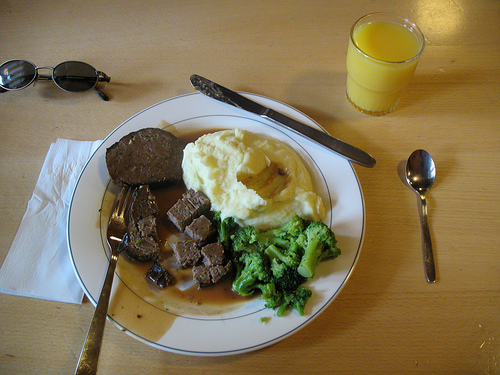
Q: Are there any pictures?
A: No, there are no pictures.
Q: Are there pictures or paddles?
A: No, there are no pictures or paddles.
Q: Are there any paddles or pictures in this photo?
A: No, there are no pictures or paddles.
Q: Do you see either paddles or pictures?
A: No, there are no pictures or paddles.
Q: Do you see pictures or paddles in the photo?
A: No, there are no pictures or paddles.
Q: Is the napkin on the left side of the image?
A: Yes, the napkin is on the left of the image.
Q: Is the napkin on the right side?
A: No, the napkin is on the left of the image.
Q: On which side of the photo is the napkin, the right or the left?
A: The napkin is on the left of the image.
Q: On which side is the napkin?
A: The napkin is on the left of the image.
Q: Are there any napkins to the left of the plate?
A: Yes, there is a napkin to the left of the plate.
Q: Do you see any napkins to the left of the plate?
A: Yes, there is a napkin to the left of the plate.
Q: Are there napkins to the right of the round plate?
A: No, the napkin is to the left of the plate.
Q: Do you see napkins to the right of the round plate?
A: No, the napkin is to the left of the plate.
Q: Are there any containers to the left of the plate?
A: No, there is a napkin to the left of the plate.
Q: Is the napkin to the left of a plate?
A: Yes, the napkin is to the left of a plate.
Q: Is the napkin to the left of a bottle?
A: No, the napkin is to the left of a plate.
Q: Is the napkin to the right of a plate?
A: No, the napkin is to the left of a plate.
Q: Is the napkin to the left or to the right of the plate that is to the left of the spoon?
A: The napkin is to the left of the plate.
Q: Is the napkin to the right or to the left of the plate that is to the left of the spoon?
A: The napkin is to the left of the plate.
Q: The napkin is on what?
A: The napkin is on the table.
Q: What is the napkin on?
A: The napkin is on the table.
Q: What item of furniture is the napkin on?
A: The napkin is on the table.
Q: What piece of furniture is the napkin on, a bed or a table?
A: The napkin is on a table.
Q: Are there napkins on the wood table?
A: Yes, there is a napkin on the table.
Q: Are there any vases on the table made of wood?
A: No, there is a napkin on the table.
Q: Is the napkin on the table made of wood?
A: Yes, the napkin is on the table.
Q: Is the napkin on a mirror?
A: No, the napkin is on the table.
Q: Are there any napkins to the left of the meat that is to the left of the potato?
A: Yes, there is a napkin to the left of the meat.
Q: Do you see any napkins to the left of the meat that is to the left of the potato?
A: Yes, there is a napkin to the left of the meat.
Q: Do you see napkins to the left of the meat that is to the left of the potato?
A: Yes, there is a napkin to the left of the meat.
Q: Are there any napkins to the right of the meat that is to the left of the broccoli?
A: No, the napkin is to the left of the meat.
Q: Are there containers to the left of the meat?
A: No, there is a napkin to the left of the meat.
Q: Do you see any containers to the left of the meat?
A: No, there is a napkin to the left of the meat.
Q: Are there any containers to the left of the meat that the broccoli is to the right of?
A: No, there is a napkin to the left of the meat.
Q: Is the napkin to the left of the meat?
A: Yes, the napkin is to the left of the meat.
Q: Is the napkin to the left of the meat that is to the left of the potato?
A: Yes, the napkin is to the left of the meat.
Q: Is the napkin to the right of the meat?
A: No, the napkin is to the left of the meat.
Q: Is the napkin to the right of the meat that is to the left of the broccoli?
A: No, the napkin is to the left of the meat.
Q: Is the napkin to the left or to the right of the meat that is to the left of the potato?
A: The napkin is to the left of the meat.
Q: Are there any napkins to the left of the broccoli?
A: Yes, there is a napkin to the left of the broccoli.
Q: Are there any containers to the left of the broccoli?
A: No, there is a napkin to the left of the broccoli.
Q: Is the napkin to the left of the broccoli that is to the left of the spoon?
A: Yes, the napkin is to the left of the broccoli.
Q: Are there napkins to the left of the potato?
A: Yes, there is a napkin to the left of the potato.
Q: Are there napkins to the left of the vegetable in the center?
A: Yes, there is a napkin to the left of the potato.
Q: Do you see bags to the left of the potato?
A: No, there is a napkin to the left of the potato.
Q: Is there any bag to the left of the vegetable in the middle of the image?
A: No, there is a napkin to the left of the potato.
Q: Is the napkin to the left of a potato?
A: Yes, the napkin is to the left of a potato.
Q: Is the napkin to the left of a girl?
A: No, the napkin is to the left of a potato.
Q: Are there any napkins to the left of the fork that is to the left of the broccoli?
A: Yes, there is a napkin to the left of the fork.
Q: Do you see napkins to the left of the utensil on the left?
A: Yes, there is a napkin to the left of the fork.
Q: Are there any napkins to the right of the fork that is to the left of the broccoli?
A: No, the napkin is to the left of the fork.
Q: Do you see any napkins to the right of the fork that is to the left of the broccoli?
A: No, the napkin is to the left of the fork.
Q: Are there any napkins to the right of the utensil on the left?
A: No, the napkin is to the left of the fork.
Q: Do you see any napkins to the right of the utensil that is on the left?
A: No, the napkin is to the left of the fork.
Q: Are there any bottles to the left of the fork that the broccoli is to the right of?
A: No, there is a napkin to the left of the fork.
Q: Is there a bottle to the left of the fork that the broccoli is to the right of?
A: No, there is a napkin to the left of the fork.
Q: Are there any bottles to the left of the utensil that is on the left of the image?
A: No, there is a napkin to the left of the fork.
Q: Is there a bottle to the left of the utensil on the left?
A: No, there is a napkin to the left of the fork.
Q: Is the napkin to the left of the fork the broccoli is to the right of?
A: Yes, the napkin is to the left of the fork.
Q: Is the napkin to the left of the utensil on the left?
A: Yes, the napkin is to the left of the fork.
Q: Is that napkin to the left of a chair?
A: No, the napkin is to the left of the fork.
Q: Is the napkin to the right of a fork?
A: No, the napkin is to the left of a fork.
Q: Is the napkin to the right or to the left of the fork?
A: The napkin is to the left of the fork.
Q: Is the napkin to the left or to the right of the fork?
A: The napkin is to the left of the fork.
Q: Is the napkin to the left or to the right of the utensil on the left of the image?
A: The napkin is to the left of the fork.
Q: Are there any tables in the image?
A: Yes, there is a table.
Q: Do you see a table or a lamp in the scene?
A: Yes, there is a table.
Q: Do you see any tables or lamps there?
A: Yes, there is a table.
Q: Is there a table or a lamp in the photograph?
A: Yes, there is a table.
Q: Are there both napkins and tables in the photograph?
A: Yes, there are both a table and a napkin.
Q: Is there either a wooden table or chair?
A: Yes, there is a wood table.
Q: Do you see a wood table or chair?
A: Yes, there is a wood table.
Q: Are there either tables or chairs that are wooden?
A: Yes, the table is wooden.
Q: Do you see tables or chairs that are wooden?
A: Yes, the table is wooden.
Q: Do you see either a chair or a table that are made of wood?
A: Yes, the table is made of wood.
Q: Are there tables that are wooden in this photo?
A: Yes, there is a wood table.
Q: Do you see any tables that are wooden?
A: Yes, there is a table that is wooden.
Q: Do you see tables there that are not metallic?
A: Yes, there is a wooden table.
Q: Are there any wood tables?
A: Yes, there is a table that is made of wood.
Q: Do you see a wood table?
A: Yes, there is a table that is made of wood.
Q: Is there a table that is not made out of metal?
A: Yes, there is a table that is made of wood.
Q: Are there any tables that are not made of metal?
A: Yes, there is a table that is made of wood.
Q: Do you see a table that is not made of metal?
A: Yes, there is a table that is made of wood.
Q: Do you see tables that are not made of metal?
A: Yes, there is a table that is made of wood.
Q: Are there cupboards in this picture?
A: No, there are no cupboards.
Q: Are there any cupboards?
A: No, there are no cupboards.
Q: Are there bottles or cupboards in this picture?
A: No, there are no cupboards or bottles.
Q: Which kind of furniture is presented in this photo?
A: The furniture is a table.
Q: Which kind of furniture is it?
A: The piece of furniture is a table.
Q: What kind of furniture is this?
A: This is a table.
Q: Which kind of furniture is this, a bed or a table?
A: This is a table.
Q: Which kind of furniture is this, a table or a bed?
A: This is a table.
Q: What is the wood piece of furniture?
A: The piece of furniture is a table.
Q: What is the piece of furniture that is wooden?
A: The piece of furniture is a table.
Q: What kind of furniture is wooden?
A: The furniture is a table.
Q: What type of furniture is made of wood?
A: The furniture is a table.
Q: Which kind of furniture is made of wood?
A: The furniture is a table.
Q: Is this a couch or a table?
A: This is a table.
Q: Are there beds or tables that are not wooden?
A: No, there is a table but it is wooden.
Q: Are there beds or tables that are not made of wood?
A: No, there is a table but it is made of wood.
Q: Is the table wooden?
A: Yes, the table is wooden.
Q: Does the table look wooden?
A: Yes, the table is wooden.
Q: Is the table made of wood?
A: Yes, the table is made of wood.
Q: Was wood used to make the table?
A: Yes, the table is made of wood.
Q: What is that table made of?
A: The table is made of wood.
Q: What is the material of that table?
A: The table is made of wood.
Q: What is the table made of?
A: The table is made of wood.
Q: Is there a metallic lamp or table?
A: No, there is a table but it is wooden.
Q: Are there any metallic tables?
A: No, there is a table but it is wooden.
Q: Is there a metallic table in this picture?
A: No, there is a table but it is wooden.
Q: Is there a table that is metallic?
A: No, there is a table but it is wooden.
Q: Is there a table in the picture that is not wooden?
A: No, there is a table but it is wooden.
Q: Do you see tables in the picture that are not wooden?
A: No, there is a table but it is wooden.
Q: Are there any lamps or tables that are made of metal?
A: No, there is a table but it is made of wood.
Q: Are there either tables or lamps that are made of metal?
A: No, there is a table but it is made of wood.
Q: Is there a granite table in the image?
A: No, there is a table but it is made of wood.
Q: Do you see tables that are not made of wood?
A: No, there is a table but it is made of wood.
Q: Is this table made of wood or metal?
A: The table is made of wood.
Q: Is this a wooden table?
A: Yes, this is a wooden table.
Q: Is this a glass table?
A: No, this is a wooden table.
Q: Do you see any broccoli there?
A: Yes, there is broccoli.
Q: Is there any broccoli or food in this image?
A: Yes, there is broccoli.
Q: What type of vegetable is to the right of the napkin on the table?
A: The vegetable is broccoli.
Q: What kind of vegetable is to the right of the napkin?
A: The vegetable is broccoli.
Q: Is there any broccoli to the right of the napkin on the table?
A: Yes, there is broccoli to the right of the napkin.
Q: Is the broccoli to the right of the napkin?
A: Yes, the broccoli is to the right of the napkin.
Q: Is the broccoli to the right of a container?
A: No, the broccoli is to the right of the napkin.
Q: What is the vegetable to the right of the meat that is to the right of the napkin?
A: The vegetable is broccoli.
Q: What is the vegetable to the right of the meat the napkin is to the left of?
A: The vegetable is broccoli.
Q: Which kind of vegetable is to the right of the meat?
A: The vegetable is broccoli.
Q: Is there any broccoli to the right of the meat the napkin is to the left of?
A: Yes, there is broccoli to the right of the meat.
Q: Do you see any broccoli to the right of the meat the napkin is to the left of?
A: Yes, there is broccoli to the right of the meat.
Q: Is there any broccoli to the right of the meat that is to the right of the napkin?
A: Yes, there is broccoli to the right of the meat.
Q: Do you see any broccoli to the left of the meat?
A: No, the broccoli is to the right of the meat.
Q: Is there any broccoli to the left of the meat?
A: No, the broccoli is to the right of the meat.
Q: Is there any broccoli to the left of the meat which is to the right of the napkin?
A: No, the broccoli is to the right of the meat.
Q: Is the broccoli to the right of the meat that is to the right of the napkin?
A: Yes, the broccoli is to the right of the meat.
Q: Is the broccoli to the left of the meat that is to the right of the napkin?
A: No, the broccoli is to the right of the meat.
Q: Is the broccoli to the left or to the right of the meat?
A: The broccoli is to the right of the meat.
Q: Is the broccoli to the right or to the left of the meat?
A: The broccoli is to the right of the meat.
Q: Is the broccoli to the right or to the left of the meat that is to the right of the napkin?
A: The broccoli is to the right of the meat.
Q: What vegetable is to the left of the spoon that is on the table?
A: The vegetable is broccoli.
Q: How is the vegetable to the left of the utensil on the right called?
A: The vegetable is broccoli.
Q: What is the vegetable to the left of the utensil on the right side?
A: The vegetable is broccoli.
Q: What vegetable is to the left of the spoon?
A: The vegetable is broccoli.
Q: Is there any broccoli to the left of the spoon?
A: Yes, there is broccoli to the left of the spoon.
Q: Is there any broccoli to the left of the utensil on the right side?
A: Yes, there is broccoli to the left of the spoon.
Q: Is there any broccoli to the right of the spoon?
A: No, the broccoli is to the left of the spoon.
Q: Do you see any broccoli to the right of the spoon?
A: No, the broccoli is to the left of the spoon.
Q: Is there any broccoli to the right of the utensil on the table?
A: No, the broccoli is to the left of the spoon.